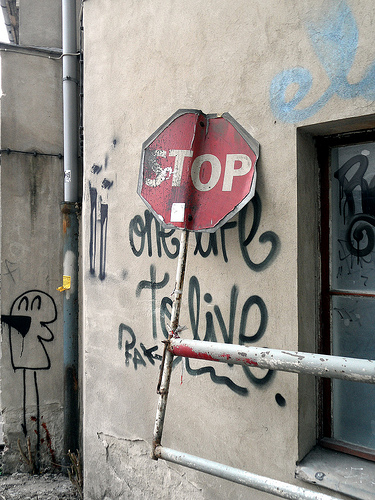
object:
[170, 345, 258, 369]
paint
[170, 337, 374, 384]
pole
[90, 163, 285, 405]
graffiti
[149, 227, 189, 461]
pole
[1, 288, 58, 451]
graffiti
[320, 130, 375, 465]
gate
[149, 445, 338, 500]
poles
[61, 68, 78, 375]
pipe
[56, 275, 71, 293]
tag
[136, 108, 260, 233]
sign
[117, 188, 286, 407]
black letters/wall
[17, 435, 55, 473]
weed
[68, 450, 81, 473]
weed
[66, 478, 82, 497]
weed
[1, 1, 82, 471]
wall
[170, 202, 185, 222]
sticker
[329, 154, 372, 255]
graffiti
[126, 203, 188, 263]
word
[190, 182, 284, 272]
word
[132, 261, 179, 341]
word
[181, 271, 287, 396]
word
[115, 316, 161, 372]
word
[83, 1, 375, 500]
building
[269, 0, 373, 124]
letters